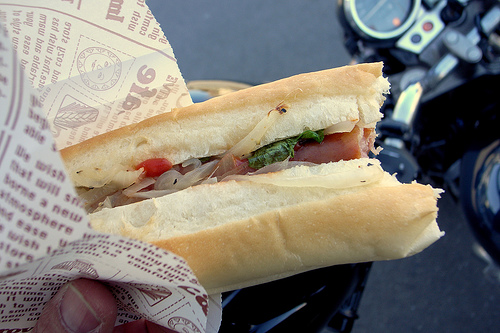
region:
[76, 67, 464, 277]
a sandwich with bread and meat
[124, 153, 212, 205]
onions in the sandwich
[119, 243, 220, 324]
paper with sandwich in it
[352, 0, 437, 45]
round meter with red and blue buttons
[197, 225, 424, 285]
bread is plain and toasted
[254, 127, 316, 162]
lettuce in the sandwich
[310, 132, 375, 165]
sandwich has ham in it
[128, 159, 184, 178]
small tomatoe on top of onion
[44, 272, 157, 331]
finger of person holding sandwich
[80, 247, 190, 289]
writing on the paper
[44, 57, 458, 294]
a sandwich on bread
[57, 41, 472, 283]
a hoagie sandwich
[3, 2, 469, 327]
a sandwich wrapped in paper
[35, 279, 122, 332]
a person's thumb holding a sandwich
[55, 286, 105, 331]
a person's thumbnil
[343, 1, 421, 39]
a gauge on a motorcycle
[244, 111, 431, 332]
the handlebar on a motorcycle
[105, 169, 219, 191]
onions on a sub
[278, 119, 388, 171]
meat on a sub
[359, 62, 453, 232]
a bite taken out of a sandwich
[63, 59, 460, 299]
partially eaten hotdog in a hand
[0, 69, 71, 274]
paper of a hotdog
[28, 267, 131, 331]
thumb of a man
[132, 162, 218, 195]
onions on a hotdog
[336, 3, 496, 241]
top of a motorcycle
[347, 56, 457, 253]
eaten area of a hotdog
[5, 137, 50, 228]
writing on a paper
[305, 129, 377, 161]
hotdog in a bun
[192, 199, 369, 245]
bread of a hotdog bun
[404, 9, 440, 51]
buttons on a motorcycle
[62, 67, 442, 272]
a sandwich in paper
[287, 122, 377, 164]
the meat of the sandwich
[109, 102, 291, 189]
onions in the sandwich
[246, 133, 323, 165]
a piece of green lettuce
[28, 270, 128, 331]
a person's thumb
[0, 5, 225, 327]
the paper wrapping on the sandwich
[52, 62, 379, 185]
the bun of the sandwich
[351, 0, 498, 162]
the handlebars of a motorcycle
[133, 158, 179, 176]
a piece of red tomato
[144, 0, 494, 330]
the gray cement ground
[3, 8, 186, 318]
paper around the hot dog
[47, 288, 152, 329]
the hand of the person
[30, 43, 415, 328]
someone holding a hot dog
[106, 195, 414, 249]
the hot dog bun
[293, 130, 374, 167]
the hot dog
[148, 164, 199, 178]
onions on the hot dog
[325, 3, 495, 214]
a motorcycle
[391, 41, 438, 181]
the handlebars on the motorcycle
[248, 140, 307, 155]
lettuce on the hot dog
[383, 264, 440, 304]
the pavement